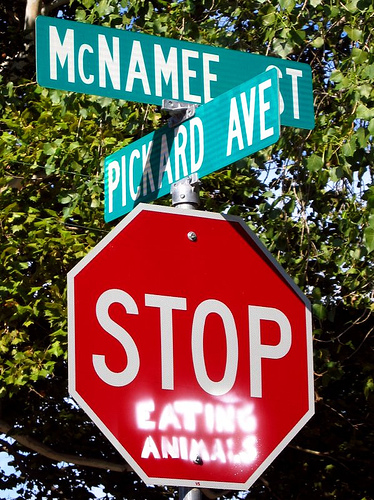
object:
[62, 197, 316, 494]
sign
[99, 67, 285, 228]
sign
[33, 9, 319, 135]
sign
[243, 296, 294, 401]
letters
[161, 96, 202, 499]
pole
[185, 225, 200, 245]
bolt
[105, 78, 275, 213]
lettering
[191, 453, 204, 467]
screw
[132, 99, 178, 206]
shadow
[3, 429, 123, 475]
limb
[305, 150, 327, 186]
leaf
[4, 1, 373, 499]
tree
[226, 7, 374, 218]
sky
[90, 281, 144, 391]
letter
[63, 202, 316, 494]
outline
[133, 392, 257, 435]
hand writing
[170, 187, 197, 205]
part